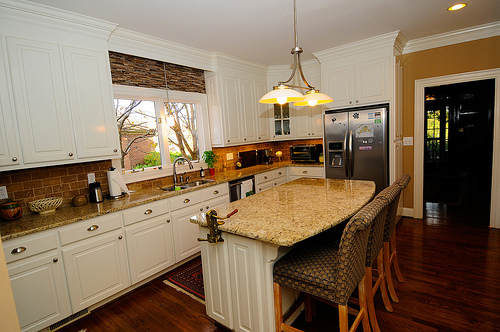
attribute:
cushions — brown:
[278, 177, 413, 297]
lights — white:
[256, 83, 334, 112]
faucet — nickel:
[172, 155, 193, 183]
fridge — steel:
[352, 105, 388, 189]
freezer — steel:
[322, 111, 346, 177]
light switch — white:
[401, 135, 414, 145]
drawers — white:
[168, 169, 228, 212]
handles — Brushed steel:
[341, 123, 356, 176]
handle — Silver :
[85, 220, 100, 234]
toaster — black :
[286, 141, 326, 171]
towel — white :
[234, 178, 258, 197]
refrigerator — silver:
[313, 110, 398, 189]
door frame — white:
[408, 66, 498, 239]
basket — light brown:
[25, 191, 65, 217]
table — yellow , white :
[190, 159, 387, 250]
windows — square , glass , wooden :
[108, 90, 212, 174]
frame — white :
[100, 69, 222, 193]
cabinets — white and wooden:
[4, 51, 91, 177]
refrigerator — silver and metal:
[332, 107, 375, 167]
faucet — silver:
[170, 149, 196, 185]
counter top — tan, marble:
[186, 175, 378, 249]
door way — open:
[412, 66, 485, 230]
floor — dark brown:
[40, 196, 481, 330]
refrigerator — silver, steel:
[319, 103, 389, 177]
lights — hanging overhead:
[259, 17, 332, 111]